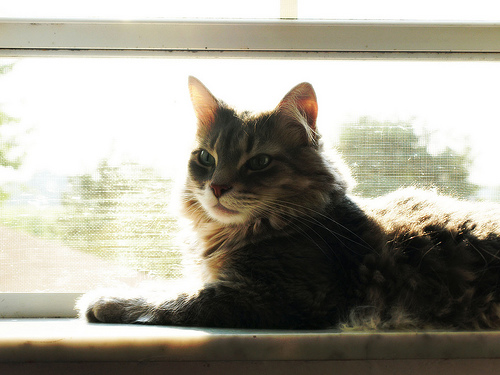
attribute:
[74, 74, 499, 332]
cat — white, looking left, grey, alert, tabby, house cat, grey color, calico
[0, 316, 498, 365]
window sill — white color, white, marbleized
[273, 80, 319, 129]
ear — glowing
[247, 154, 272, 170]
eye — yellow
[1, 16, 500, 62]
window frame — white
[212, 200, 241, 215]
mouth — closed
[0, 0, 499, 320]
window — white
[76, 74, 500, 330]
fur — longer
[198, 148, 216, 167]
eye — green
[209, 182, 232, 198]
nose — pink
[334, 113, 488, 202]
tree — green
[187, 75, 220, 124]
ear — pink, perked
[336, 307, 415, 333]
belly fur — white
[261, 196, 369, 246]
whisker — long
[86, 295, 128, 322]
paw — lighter colored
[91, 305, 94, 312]
claw — grey